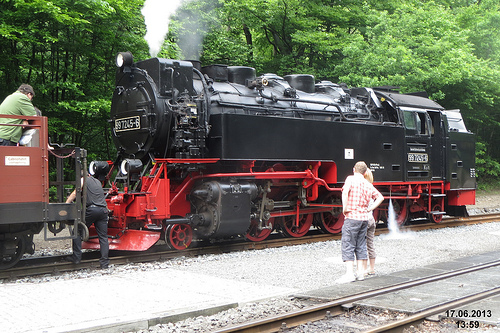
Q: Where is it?
A: This is at the forest.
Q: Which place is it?
A: It is a forest.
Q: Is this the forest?
A: Yes, it is the forest.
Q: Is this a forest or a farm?
A: It is a forest.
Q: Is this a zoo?
A: No, it is a forest.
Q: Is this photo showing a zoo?
A: No, the picture is showing a forest.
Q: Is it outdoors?
A: Yes, it is outdoors.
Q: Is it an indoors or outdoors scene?
A: It is outdoors.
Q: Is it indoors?
A: No, it is outdoors.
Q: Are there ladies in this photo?
A: No, there are no ladies.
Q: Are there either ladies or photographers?
A: No, there are no ladies or photographers.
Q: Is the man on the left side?
A: Yes, the man is on the left of the image.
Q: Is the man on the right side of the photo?
A: No, the man is on the left of the image.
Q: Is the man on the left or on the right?
A: The man is on the left of the image.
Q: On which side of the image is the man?
A: The man is on the left of the image.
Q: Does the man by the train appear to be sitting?
A: Yes, the man is sitting.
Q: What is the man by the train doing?
A: The man is sitting.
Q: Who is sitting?
A: The man is sitting.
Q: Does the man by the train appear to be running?
A: No, the man is sitting.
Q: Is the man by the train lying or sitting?
A: The man is sitting.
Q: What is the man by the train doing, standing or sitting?
A: The man is sitting.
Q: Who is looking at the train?
A: The man is looking at the train.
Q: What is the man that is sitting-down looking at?
A: The man is looking at the train.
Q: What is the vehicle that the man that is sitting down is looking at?
A: The vehicle is a train.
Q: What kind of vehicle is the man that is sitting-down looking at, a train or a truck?
A: The man is looking at a train.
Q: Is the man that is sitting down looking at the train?
A: Yes, the man is looking at the train.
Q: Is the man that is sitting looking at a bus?
A: No, the man is looking at the train.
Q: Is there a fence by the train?
A: No, there is a man by the train.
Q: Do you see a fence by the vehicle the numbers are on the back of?
A: No, there is a man by the train.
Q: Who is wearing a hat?
A: The man is wearing a hat.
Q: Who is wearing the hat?
A: The man is wearing a hat.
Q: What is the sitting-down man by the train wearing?
A: The man is wearing a hat.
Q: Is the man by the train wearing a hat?
A: Yes, the man is wearing a hat.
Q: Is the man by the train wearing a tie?
A: No, the man is wearing a hat.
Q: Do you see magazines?
A: No, there are no magazines.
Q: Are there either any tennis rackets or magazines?
A: No, there are no magazines or tennis rackets.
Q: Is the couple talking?
A: Yes, the couple is talking.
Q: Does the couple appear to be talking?
A: Yes, the couple is talking.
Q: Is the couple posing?
A: No, the couple is talking.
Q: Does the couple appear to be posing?
A: No, the couple is talking.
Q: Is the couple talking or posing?
A: The couple is talking.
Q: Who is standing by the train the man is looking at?
A: The couple is standing by the train.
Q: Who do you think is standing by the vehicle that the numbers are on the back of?
A: The couple is standing by the train.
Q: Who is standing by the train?
A: The couple is standing by the train.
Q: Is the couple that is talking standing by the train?
A: Yes, the couple is standing by the train.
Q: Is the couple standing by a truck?
A: No, the couple is standing by the train.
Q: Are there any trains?
A: Yes, there is a train.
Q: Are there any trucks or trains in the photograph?
A: Yes, there is a train.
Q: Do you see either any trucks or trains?
A: Yes, there is a train.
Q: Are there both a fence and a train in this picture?
A: No, there is a train but no fences.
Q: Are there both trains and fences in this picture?
A: No, there is a train but no fences.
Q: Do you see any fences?
A: No, there are no fences.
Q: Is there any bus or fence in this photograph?
A: No, there are no fences or buses.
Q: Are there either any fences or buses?
A: No, there are no fences or buses.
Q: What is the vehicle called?
A: The vehicle is a train.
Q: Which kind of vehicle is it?
A: The vehicle is a train.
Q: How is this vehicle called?
A: This is a train.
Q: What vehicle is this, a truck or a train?
A: This is a train.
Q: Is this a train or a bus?
A: This is a train.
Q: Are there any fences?
A: No, there are no fences.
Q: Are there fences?
A: No, there are no fences.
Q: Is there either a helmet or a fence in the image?
A: No, there are no fences or helmets.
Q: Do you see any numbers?
A: Yes, there are numbers.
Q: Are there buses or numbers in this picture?
A: Yes, there are numbers.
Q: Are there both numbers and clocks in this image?
A: No, there are numbers but no clocks.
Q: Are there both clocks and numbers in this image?
A: No, there are numbers but no clocks.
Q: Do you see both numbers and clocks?
A: No, there are numbers but no clocks.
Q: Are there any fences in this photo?
A: No, there are no fences.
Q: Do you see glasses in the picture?
A: No, there are no glasses.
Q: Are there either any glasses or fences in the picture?
A: No, there are no glasses or fences.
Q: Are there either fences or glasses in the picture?
A: No, there are no glasses or fences.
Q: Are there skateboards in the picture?
A: No, there are no skateboards.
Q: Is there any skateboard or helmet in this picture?
A: No, there are no skateboards or helmets.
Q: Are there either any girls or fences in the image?
A: No, there are no fences or girls.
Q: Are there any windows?
A: Yes, there is a window.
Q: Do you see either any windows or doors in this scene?
A: Yes, there is a window.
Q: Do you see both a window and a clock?
A: No, there is a window but no clocks.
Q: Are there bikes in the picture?
A: No, there are no bikes.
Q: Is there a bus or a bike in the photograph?
A: No, there are no bikes or buses.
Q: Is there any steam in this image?
A: Yes, there is steam.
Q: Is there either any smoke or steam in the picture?
A: Yes, there is steam.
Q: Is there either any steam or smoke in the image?
A: Yes, there is steam.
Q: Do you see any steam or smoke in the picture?
A: Yes, there is steam.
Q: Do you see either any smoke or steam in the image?
A: Yes, there is steam.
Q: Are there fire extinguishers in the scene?
A: No, there are no fire extinguishers.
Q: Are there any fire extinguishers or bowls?
A: No, there are no fire extinguishers or bowls.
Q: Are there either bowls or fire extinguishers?
A: No, there are no fire extinguishers or bowls.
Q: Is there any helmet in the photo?
A: No, there are no helmets.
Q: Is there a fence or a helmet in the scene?
A: No, there are no helmets or fences.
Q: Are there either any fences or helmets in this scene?
A: No, there are no helmets or fences.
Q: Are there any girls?
A: No, there are no girls.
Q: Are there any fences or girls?
A: No, there are no girls or fences.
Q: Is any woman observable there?
A: No, there are no women.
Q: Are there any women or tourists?
A: No, there are no women or tourists.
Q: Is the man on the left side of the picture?
A: Yes, the man is on the left of the image.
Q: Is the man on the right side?
A: No, the man is on the left of the image.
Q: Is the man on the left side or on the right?
A: The man is on the left of the image.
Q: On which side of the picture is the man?
A: The man is on the left of the image.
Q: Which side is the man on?
A: The man is on the left of the image.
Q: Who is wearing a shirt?
A: The man is wearing a shirt.